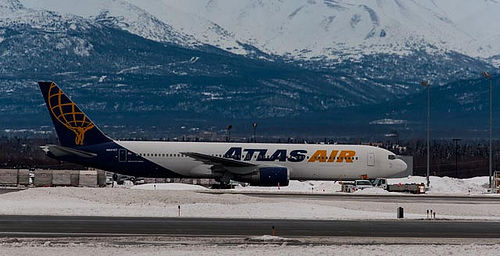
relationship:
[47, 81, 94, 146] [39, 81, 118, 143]
logo on tail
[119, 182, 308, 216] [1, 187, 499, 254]
snow on runway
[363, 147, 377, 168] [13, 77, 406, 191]
door on airplane